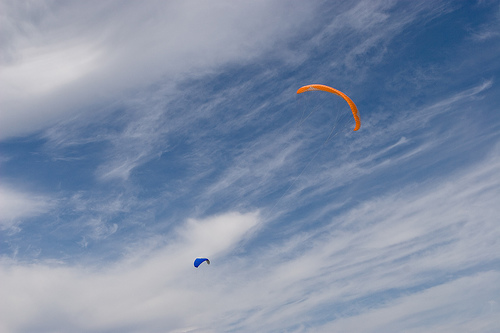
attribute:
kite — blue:
[185, 248, 215, 270]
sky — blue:
[0, 5, 496, 328]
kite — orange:
[294, 76, 366, 134]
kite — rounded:
[292, 80, 362, 137]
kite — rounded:
[187, 249, 218, 272]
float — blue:
[191, 254, 211, 270]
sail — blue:
[193, 257, 210, 267]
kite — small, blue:
[133, 233, 271, 305]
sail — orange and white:
[293, 77, 365, 134]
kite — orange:
[293, 78, 372, 148]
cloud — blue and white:
[4, 208, 263, 332]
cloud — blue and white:
[309, 264, 498, 331]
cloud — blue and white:
[3, 34, 125, 116]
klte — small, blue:
[193, 256, 209, 272]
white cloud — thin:
[96, 155, 144, 177]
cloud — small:
[4, 180, 49, 215]